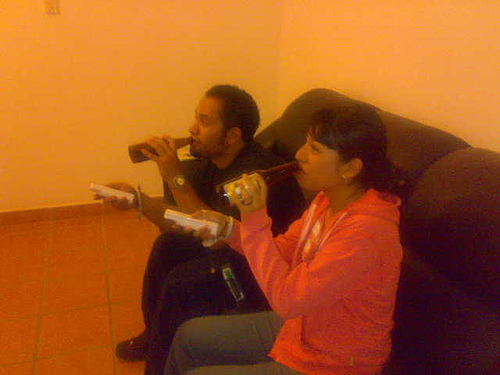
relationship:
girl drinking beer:
[169, 104, 407, 373] [214, 162, 303, 210]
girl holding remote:
[169, 104, 407, 373] [166, 203, 218, 236]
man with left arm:
[120, 85, 298, 357] [150, 139, 237, 249]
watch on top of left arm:
[166, 175, 191, 189] [150, 139, 237, 249]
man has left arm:
[120, 85, 298, 357] [150, 139, 237, 249]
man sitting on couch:
[93, 84, 308, 375] [179, 86, 497, 372]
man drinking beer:
[93, 84, 308, 375] [132, 136, 298, 199]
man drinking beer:
[120, 85, 298, 357] [127, 139, 197, 160]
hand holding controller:
[106, 183, 138, 210] [93, 185, 135, 205]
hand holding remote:
[188, 212, 230, 237] [166, 203, 218, 236]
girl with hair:
[169, 104, 407, 373] [319, 108, 406, 189]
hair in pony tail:
[319, 108, 406, 189] [375, 155, 407, 198]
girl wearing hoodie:
[169, 104, 407, 373] [243, 189, 398, 370]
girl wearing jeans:
[169, 104, 407, 373] [171, 312, 318, 373]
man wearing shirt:
[120, 85, 298, 357] [198, 138, 304, 235]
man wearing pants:
[120, 85, 298, 357] [143, 235, 232, 343]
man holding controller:
[120, 85, 298, 357] [93, 185, 135, 205]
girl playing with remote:
[169, 104, 407, 373] [166, 203, 218, 236]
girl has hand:
[169, 104, 407, 373] [233, 177, 267, 212]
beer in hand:
[214, 162, 303, 210] [233, 177, 267, 212]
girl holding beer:
[169, 104, 407, 373] [214, 162, 303, 210]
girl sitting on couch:
[169, 104, 407, 373] [179, 86, 497, 372]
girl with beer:
[169, 104, 407, 373] [214, 162, 303, 210]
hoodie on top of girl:
[243, 189, 398, 370] [169, 104, 407, 373]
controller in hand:
[93, 185, 135, 205] [106, 183, 138, 210]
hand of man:
[106, 183, 138, 210] [120, 85, 298, 357]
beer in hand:
[127, 139, 197, 160] [149, 140, 181, 174]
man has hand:
[120, 85, 298, 357] [149, 140, 181, 174]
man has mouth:
[120, 85, 298, 357] [189, 135, 201, 145]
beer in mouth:
[127, 139, 197, 160] [189, 135, 201, 145]